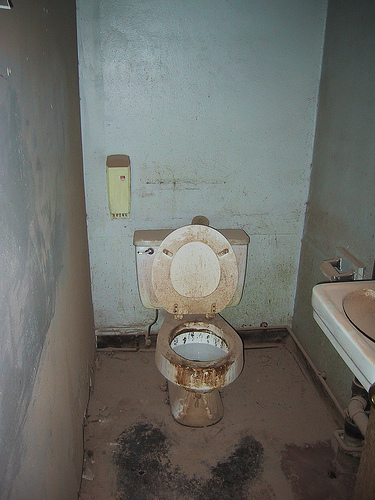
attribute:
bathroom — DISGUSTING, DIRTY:
[20, 28, 362, 490]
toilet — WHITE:
[130, 218, 252, 446]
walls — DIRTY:
[31, 93, 79, 342]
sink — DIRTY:
[318, 279, 363, 362]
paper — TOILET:
[319, 261, 342, 285]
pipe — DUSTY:
[349, 403, 359, 427]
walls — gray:
[2, 1, 374, 498]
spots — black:
[109, 420, 266, 492]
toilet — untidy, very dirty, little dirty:
[133, 224, 251, 429]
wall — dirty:
[0, 2, 373, 498]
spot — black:
[113, 424, 265, 494]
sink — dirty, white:
[310, 274, 374, 389]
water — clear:
[171, 341, 227, 362]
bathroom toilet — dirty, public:
[132, 222, 251, 427]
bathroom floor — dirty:
[81, 342, 357, 496]